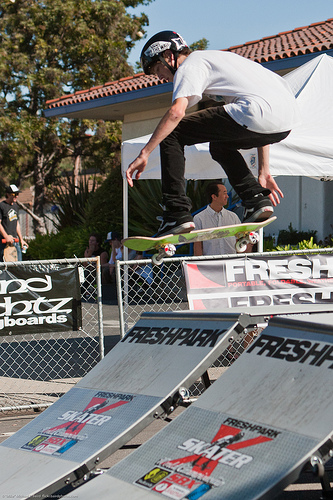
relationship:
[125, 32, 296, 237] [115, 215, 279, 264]
man on a skateboard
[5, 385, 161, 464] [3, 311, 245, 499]
sticker on a ramp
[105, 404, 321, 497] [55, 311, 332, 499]
sticker on a ramp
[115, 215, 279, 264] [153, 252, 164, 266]
skateboard has a wheel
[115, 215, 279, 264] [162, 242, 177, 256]
skateboard has a wheel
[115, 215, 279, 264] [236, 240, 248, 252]
skateboard has a wheel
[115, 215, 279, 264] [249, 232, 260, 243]
skateboard has a wheel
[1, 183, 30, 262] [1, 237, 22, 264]
man holding skateboard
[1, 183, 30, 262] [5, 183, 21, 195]
man wearing a hat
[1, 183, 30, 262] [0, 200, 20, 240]
man wearing a shirt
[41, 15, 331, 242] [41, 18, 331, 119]
building has a roof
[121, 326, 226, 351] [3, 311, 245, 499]
logo on a ramp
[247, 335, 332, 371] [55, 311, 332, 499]
logo on a ramp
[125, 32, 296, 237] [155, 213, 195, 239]
man wearing a shoe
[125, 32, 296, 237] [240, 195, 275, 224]
man wearing a shoe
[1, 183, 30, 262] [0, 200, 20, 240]
man wearing shirt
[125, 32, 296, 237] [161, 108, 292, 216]
man wearing pants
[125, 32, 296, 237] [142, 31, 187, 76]
man wearing a helmet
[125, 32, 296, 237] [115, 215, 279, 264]
man with a skateboard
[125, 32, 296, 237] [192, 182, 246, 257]
man behind man